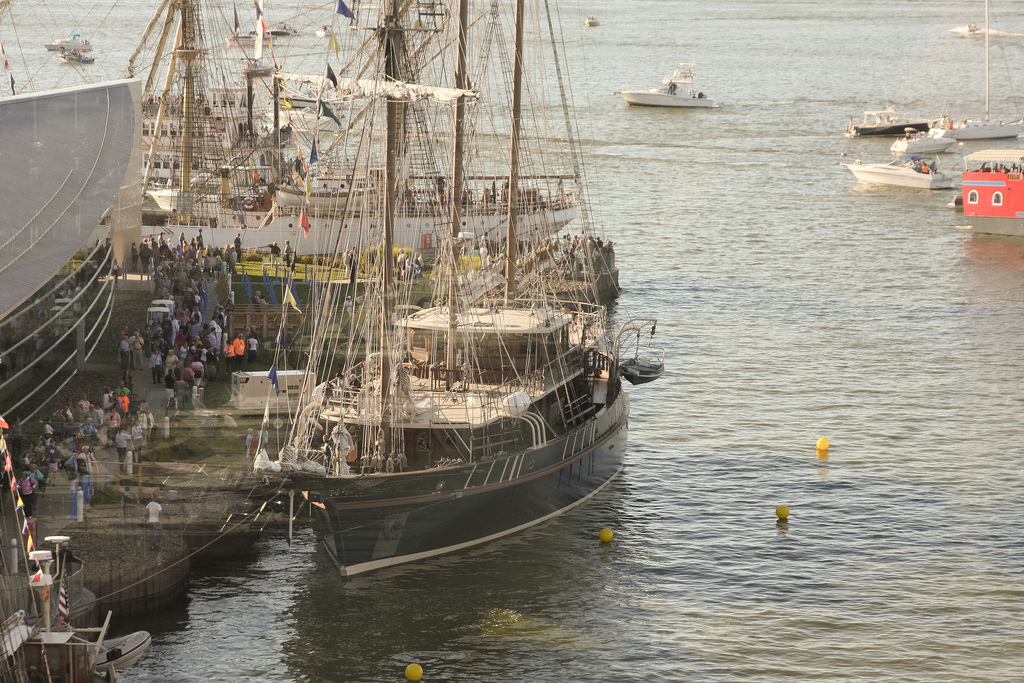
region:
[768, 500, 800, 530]
A yellow ball floating on the water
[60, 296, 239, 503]
a group of people on a walkway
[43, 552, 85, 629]
the american flag on a boat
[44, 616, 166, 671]
a light colored dinghy strapped to a boat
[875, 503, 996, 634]
a few ripples in the water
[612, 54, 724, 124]
a small white speed boat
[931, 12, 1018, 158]
a small white sail boat on the water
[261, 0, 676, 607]
a large blue ship tied to the dock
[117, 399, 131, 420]
person on the dock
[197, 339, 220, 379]
person on the dock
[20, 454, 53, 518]
person on the dock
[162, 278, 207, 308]
person on the dock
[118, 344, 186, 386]
person on the dock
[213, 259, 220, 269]
person on the dock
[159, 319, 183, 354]
person on the dock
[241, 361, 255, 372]
person on the dock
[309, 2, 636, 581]
a pirate ship in the sea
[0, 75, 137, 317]
an open sail on a pirate ship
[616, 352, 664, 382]
a dinghy on the side of a boat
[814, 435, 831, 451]
buoy floating in the water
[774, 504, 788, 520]
buoy floating in the water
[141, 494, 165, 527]
a man on the dock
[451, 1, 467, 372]
pole for a sail on a boat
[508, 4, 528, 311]
pole for a sail on a boat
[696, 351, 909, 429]
water is dark grey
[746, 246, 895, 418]
small ripples on water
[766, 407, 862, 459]
yellow buoy in water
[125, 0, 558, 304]
grey masts on boat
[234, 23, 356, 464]
colorful flags on line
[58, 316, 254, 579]
pier is light grey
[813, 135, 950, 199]
small and white boat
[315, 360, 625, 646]
a boat in the water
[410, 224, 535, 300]
a boat in the water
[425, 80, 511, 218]
a boat in the water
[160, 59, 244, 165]
a boat in the water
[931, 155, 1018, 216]
a boat in the water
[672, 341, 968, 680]
a body of water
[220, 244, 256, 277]
a person standing on a boat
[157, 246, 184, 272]
a person standing on a boat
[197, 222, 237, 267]
a person standing on a boat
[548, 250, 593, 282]
a person standing on a boat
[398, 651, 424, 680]
yellow ball in water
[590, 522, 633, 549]
yellow ball in water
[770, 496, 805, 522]
yellow ball in water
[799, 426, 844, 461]
yellow ball in water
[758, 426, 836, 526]
yellow balls in water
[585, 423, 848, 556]
yellow balls in water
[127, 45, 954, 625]
this is a harbor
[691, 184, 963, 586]
the water is calm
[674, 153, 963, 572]
the water is blue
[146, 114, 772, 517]
this is a ship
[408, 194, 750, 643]
the ship is docked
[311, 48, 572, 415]
the masts are tall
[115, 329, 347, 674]
this is the dock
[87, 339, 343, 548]
the dock is wooden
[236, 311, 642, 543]
the boat is gray